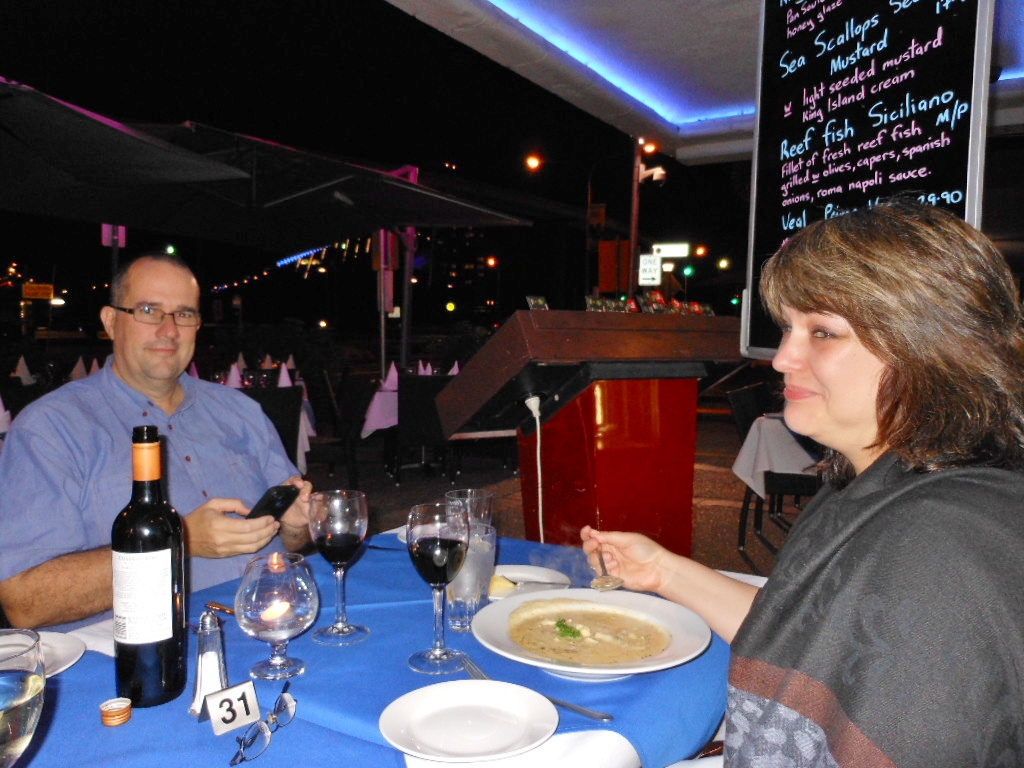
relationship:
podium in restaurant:
[412, 312, 736, 546] [13, 19, 1012, 748]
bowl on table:
[467, 581, 712, 679] [4, 531, 739, 766]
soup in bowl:
[507, 603, 681, 670] [467, 581, 712, 679]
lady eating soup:
[689, 207, 1021, 768] [507, 603, 681, 670]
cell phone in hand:
[242, 483, 301, 522] [201, 502, 275, 554]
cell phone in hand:
[242, 483, 301, 522] [281, 489, 323, 533]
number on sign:
[219, 692, 254, 727] [206, 678, 264, 735]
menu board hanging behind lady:
[734, 0, 1001, 365] [689, 207, 1021, 768]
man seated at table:
[0, 259, 297, 612] [4, 531, 739, 766]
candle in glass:
[232, 591, 316, 637] [232, 546, 324, 680]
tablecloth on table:
[302, 576, 400, 694] [113, 547, 753, 764]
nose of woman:
[767, 320, 810, 372] [755, 237, 1019, 478]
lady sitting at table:
[739, 207, 1022, 474] [281, 500, 775, 747]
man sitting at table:
[0, 259, 297, 612] [227, 472, 769, 755]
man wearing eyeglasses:
[87, 259, 220, 402] [98, 298, 213, 330]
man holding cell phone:
[87, 259, 220, 402] [227, 468, 307, 538]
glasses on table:
[284, 465, 496, 681] [227, 472, 769, 755]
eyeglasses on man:
[98, 298, 213, 330] [98, 264, 216, 385]